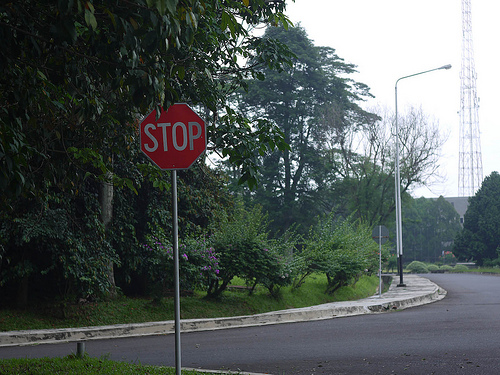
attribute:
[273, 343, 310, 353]
road — grey, gray, paved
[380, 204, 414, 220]
poles — grey, gray, metal, silver, tall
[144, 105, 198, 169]
sign board — red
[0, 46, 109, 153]
trees — green, pine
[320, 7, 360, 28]
sky — white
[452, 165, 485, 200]
tower — one, tall, background, metal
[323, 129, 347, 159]
scene — day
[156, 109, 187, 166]
sign — red, stop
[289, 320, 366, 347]
street — long, empty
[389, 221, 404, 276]
light — tall, off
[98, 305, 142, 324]
grass — green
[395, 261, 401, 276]
paint — black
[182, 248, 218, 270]
flowers — purple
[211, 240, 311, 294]
bushes — purple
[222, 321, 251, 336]
curb — dirty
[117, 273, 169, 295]
shrubs — green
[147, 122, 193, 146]
lettering — white